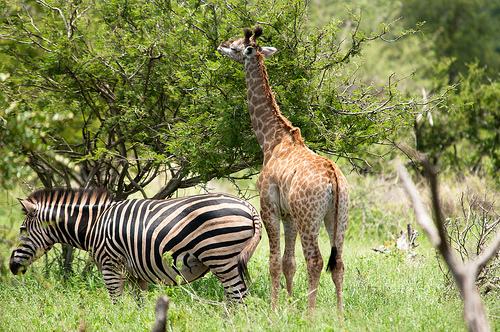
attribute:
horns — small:
[236, 15, 285, 69]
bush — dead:
[404, 181, 495, 281]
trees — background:
[399, 6, 495, 201]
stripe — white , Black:
[164, 204, 253, 253]